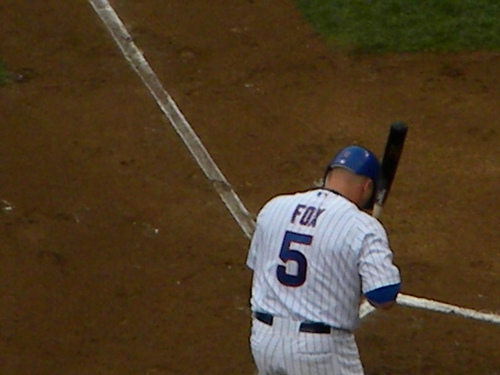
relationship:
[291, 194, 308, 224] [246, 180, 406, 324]
letter on jersey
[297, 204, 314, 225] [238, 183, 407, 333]
letter on jersey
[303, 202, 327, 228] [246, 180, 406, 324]
letter on jersey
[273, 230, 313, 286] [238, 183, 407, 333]
5 on jersey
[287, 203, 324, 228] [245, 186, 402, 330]
fox written on jersey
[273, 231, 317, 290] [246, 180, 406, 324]
5 on back of jersey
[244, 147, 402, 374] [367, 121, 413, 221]
batter holding bat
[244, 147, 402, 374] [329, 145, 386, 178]
batter wearing helmet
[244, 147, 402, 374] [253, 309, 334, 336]
batter wearing belt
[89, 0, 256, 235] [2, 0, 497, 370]
line in dirt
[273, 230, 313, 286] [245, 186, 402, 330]
5 on jersey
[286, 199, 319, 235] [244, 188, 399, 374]
fox on uniform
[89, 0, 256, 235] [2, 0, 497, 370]
line on dirt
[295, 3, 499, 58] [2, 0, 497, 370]
grass patch near dirt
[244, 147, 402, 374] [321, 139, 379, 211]
batter has head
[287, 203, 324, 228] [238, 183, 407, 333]
fox on jersey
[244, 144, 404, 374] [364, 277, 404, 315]
batter has elbow